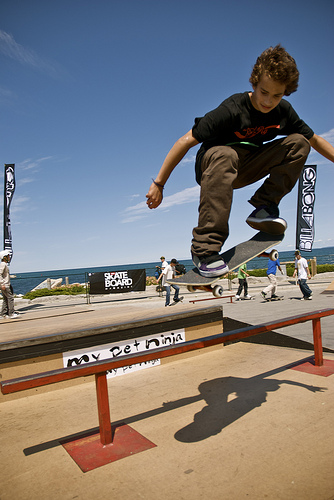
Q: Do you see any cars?
A: No, there are no cars.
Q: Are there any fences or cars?
A: No, there are no cars or fences.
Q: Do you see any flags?
A: Yes, there is a flag.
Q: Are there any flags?
A: Yes, there is a flag.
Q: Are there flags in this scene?
A: Yes, there is a flag.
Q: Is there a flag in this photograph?
A: Yes, there is a flag.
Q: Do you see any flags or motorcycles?
A: Yes, there is a flag.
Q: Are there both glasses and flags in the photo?
A: No, there is a flag but no glasses.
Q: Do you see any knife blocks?
A: No, there are no knife blocks.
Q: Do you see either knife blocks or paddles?
A: No, there are no knife blocks or paddles.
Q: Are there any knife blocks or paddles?
A: No, there are no knife blocks or paddles.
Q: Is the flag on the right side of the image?
A: Yes, the flag is on the right of the image.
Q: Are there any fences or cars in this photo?
A: No, there are no fences or cars.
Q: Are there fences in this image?
A: No, there are no fences.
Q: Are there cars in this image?
A: No, there are no cars.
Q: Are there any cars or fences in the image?
A: No, there are no cars or fences.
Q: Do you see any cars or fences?
A: No, there are no cars or fences.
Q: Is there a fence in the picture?
A: No, there are no fences.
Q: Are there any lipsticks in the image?
A: No, there are no lipsticks.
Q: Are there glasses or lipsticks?
A: No, there are no lipsticks or glasses.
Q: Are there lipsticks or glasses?
A: No, there are no lipsticks or glasses.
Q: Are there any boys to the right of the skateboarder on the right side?
A: Yes, there is a boy to the right of the skateboarder.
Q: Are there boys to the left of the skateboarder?
A: No, the boy is to the right of the skateboarder.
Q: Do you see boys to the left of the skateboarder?
A: No, the boy is to the right of the skateboarder.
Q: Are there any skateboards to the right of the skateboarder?
A: No, there is a boy to the right of the skateboarder.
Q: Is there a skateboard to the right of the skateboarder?
A: No, there is a boy to the right of the skateboarder.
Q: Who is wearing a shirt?
A: The boy is wearing a shirt.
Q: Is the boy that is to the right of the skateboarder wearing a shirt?
A: Yes, the boy is wearing a shirt.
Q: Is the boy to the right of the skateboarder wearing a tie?
A: No, the boy is wearing a shirt.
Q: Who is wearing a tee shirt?
A: The boy is wearing a tee shirt.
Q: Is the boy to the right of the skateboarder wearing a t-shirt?
A: Yes, the boy is wearing a t-shirt.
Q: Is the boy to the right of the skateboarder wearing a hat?
A: No, the boy is wearing a t-shirt.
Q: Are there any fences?
A: No, there are no fences.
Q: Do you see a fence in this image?
A: No, there are no fences.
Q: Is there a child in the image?
A: Yes, there is a child.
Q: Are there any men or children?
A: Yes, there is a child.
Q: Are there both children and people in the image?
A: Yes, there are both a child and a person.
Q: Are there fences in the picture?
A: No, there are no fences.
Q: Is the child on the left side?
A: Yes, the child is on the left of the image.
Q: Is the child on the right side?
A: No, the child is on the left of the image.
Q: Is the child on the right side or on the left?
A: The child is on the left of the image.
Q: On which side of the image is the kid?
A: The kid is on the left of the image.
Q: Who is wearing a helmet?
A: The child is wearing a helmet.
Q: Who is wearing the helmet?
A: The child is wearing a helmet.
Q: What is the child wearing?
A: The child is wearing a helmet.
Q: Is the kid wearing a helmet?
A: Yes, the kid is wearing a helmet.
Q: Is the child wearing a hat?
A: No, the child is wearing a helmet.